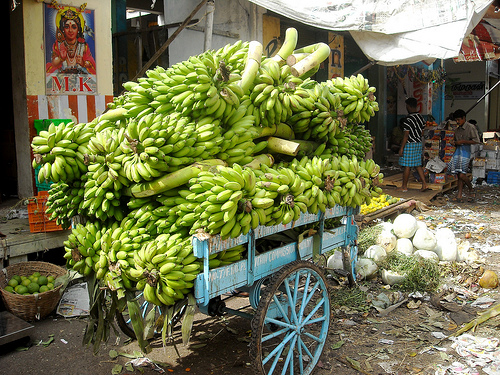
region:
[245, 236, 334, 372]
large wheel on a cart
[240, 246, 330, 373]
large blue wheel on a cart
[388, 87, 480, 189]
people near a large blue cart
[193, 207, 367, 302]
side of a large blue cart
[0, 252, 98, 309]
basket of limes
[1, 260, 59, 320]
basket sitting on the ground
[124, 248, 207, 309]
fruit in a cart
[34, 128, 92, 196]
bushel of bananas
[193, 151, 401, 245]
bananas in a cart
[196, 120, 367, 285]
bushels of bananas in a blue cart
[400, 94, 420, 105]
a black baseball cap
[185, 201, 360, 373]
part of a blue cart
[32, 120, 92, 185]
a bunch of green unripe bananas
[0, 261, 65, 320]
a basket of green fruit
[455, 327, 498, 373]
a pile of debris in the street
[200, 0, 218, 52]
a white pole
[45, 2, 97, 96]
a colorful poster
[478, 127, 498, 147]
an opened box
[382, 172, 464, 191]
part of a wooden crate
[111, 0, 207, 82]
a long piece of wood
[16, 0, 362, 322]
the bananas are green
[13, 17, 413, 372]
bananas are in cart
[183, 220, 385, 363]
the cart is blue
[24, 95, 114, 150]
wall is red and white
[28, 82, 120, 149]
the wall is striped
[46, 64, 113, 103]
the poster says M.K.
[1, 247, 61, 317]
basket of fruit on ground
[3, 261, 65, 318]
the fruit is green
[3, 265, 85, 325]
the basket is brown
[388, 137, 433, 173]
person wearing blue skirt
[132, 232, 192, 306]
a bunch of yellow green bananas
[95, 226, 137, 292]
a bunch of yellow green bananas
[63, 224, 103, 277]
a bunch of yellow green bananas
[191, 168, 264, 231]
a bunch of yellow green bananas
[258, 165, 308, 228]
a bunch of yellow green bananas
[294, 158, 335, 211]
a bunch of yellow green bananas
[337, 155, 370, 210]
a bunch of yellow green bananas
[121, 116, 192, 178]
a bunch of yellow green bananas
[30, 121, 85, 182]
a bunch of yellow green bananas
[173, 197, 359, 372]
a light blue cart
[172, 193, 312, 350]
the bananas are green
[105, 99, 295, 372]
the bananas are green